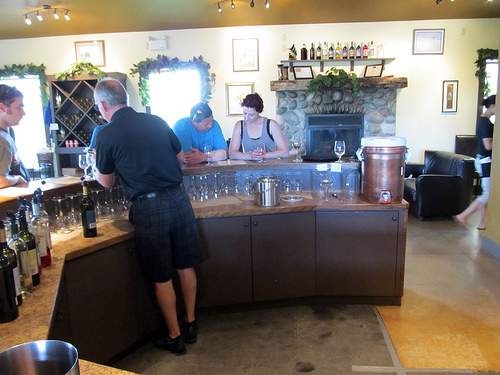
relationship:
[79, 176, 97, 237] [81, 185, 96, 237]
alcohol of alcohol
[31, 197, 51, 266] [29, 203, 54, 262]
alcohol of alcohol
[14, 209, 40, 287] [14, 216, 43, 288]
alcohol of alcohol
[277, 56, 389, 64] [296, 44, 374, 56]
shelf has bottles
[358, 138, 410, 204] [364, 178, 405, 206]
dispenser for beverages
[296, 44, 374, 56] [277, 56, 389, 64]
bottles on shelf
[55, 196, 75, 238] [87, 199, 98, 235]
glass for wine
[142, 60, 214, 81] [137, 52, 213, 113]
wreath around window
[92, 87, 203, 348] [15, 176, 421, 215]
bartender behind bar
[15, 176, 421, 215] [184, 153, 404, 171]
bar has counter